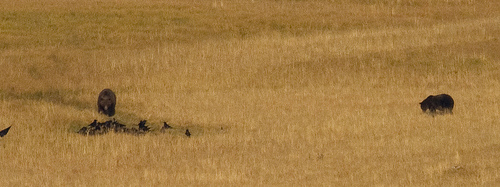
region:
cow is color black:
[408, 81, 460, 124]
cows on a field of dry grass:
[6, 5, 495, 183]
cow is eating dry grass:
[86, 83, 126, 122]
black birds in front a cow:
[0, 85, 195, 146]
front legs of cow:
[429, 103, 441, 113]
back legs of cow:
[444, 105, 456, 116]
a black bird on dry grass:
[179, 123, 196, 141]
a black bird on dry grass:
[157, 117, 177, 134]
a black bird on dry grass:
[75, 118, 89, 138]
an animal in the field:
[413, 87, 464, 114]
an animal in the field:
[90, 85, 122, 114]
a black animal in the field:
[420, 92, 466, 106]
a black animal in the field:
[93, 87, 117, 109]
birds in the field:
[160, 119, 198, 144]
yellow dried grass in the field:
[206, 34, 338, 114]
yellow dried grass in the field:
[366, 136, 483, 185]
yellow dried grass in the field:
[15, 7, 140, 59]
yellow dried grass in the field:
[49, 158, 155, 185]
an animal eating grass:
[412, 91, 460, 111]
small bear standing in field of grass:
[399, 81, 469, 126]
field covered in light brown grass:
[254, 20, 398, 159]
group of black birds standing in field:
[133, 113, 220, 151]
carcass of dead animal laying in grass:
[67, 115, 149, 147]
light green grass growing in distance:
[6, 0, 183, 46]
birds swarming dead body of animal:
[72, 113, 217, 152]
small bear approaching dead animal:
[67, 78, 133, 118]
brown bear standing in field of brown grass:
[85, 82, 131, 117]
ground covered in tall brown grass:
[228, 15, 410, 185]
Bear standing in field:
[420, 93, 455, 113]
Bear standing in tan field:
[96, 87, 121, 117]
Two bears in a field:
[80, 81, 455, 118]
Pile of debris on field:
[70, 115, 134, 136]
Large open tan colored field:
[2, 0, 497, 185]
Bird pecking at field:
[1, 122, 12, 137]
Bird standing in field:
[180, 121, 190, 136]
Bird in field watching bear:
[160, 118, 173, 129]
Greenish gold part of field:
[12, 9, 270, 41]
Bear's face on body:
[101, 95, 114, 112]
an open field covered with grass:
[3, 0, 498, 180]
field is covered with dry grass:
[2, 5, 492, 182]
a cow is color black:
[410, 80, 461, 120]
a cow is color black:
[85, 80, 120, 115]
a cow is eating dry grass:
[91, 81, 120, 120]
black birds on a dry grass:
[1, 113, 209, 149]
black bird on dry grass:
[180, 121, 194, 142]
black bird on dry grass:
[159, 117, 174, 134]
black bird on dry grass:
[81, 115, 103, 132]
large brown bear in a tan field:
[95, 85, 116, 117]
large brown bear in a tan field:
[419, 89, 454, 115]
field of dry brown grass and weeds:
[2, 2, 499, 184]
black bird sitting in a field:
[159, 118, 172, 133]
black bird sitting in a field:
[181, 124, 192, 138]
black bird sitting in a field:
[88, 116, 99, 128]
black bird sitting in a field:
[1, 120, 16, 142]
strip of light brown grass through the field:
[85, 16, 497, 61]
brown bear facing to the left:
[418, 91, 455, 116]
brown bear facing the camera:
[95, 84, 119, 117]